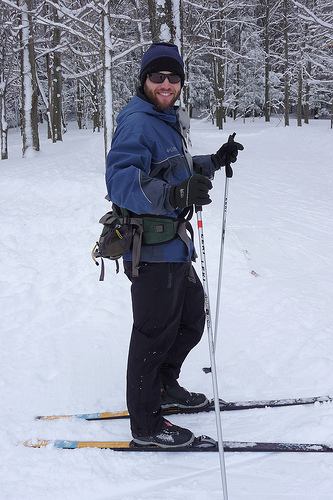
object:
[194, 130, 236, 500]
skis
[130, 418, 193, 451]
sneaker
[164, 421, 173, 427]
lace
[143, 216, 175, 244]
fanny pack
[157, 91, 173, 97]
grin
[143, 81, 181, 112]
beard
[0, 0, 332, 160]
trees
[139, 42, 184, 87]
ski cap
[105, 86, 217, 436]
clothes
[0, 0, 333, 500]
snow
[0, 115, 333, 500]
ground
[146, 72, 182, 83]
glasses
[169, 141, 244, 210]
gloves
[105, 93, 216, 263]
jacket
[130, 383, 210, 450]
man's feet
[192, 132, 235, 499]
poles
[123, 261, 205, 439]
ski pants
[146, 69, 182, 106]
man's face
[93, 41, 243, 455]
skier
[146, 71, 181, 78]
frames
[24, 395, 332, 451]
skis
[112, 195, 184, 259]
man's waist